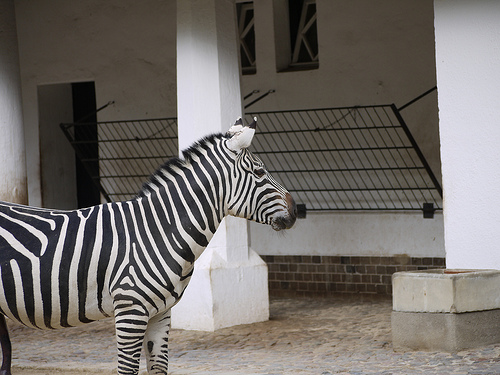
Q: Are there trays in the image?
A: No, there are no trays.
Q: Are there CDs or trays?
A: No, there are no trays or cds.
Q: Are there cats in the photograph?
A: No, there are no cats.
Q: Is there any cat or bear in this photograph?
A: No, there are no cats or bears.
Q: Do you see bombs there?
A: No, there are no bombs.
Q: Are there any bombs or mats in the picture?
A: No, there are no bombs or mats.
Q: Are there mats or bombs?
A: No, there are no bombs or mats.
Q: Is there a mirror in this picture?
A: No, there are no mirrors.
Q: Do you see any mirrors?
A: No, there are no mirrors.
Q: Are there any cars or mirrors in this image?
A: No, there are no mirrors or cars.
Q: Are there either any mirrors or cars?
A: No, there are no mirrors or cars.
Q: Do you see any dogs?
A: No, there are no dogs.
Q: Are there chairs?
A: No, there are no chairs.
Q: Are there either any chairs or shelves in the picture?
A: No, there are no chairs or shelves.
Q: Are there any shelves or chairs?
A: No, there are no chairs or shelves.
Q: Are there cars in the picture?
A: No, there are no cars.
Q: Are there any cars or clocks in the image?
A: No, there are no cars or clocks.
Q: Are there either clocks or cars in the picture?
A: No, there are no cars or clocks.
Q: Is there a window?
A: Yes, there is a window.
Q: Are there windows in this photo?
A: Yes, there is a window.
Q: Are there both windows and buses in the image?
A: No, there is a window but no buses.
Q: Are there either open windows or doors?
A: Yes, there is an open window.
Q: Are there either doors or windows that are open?
A: Yes, the window is open.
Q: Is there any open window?
A: Yes, there is an open window.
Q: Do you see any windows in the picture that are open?
A: Yes, there is a window that is open.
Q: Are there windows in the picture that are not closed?
A: Yes, there is a open window.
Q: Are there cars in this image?
A: No, there are no cars.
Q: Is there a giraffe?
A: No, there are no giraffes.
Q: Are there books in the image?
A: No, there are no books.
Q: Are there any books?
A: No, there are no books.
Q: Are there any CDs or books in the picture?
A: No, there are no books or cds.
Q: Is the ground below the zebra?
A: Yes, the ground is below the zebra.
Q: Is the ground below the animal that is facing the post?
A: Yes, the ground is below the zebra.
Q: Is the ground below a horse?
A: No, the ground is below the zebra.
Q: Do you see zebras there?
A: Yes, there is a zebra.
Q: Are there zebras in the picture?
A: Yes, there is a zebra.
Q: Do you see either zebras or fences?
A: Yes, there is a zebra.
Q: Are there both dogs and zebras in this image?
A: No, there is a zebra but no dogs.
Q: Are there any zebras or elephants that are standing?
A: Yes, the zebra is standing.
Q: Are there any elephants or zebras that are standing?
A: Yes, the zebra is standing.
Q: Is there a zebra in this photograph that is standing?
A: Yes, there is a zebra that is standing.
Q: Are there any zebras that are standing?
A: Yes, there is a zebra that is standing.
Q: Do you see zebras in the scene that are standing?
A: Yes, there is a zebra that is standing.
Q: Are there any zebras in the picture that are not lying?
A: Yes, there is a zebra that is standing.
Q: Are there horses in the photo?
A: No, there are no horses.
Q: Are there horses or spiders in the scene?
A: No, there are no horses or spiders.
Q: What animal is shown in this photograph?
A: The animal is a zebra.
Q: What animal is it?
A: The animal is a zebra.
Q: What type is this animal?
A: This is a zebra.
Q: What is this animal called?
A: This is a zebra.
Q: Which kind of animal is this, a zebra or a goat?
A: This is a zebra.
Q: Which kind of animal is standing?
A: The animal is a zebra.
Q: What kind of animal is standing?
A: The animal is a zebra.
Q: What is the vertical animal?
A: The animal is a zebra.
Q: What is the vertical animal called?
A: The animal is a zebra.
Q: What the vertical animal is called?
A: The animal is a zebra.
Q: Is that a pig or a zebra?
A: That is a zebra.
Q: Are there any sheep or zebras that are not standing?
A: No, there is a zebra but it is standing.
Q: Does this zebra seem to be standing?
A: Yes, the zebra is standing.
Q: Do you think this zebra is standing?
A: Yes, the zebra is standing.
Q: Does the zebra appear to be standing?
A: Yes, the zebra is standing.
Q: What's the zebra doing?
A: The zebra is standing.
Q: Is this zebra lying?
A: No, the zebra is standing.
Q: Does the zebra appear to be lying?
A: No, the zebra is standing.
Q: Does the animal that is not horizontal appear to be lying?
A: No, the zebra is standing.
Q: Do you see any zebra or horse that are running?
A: No, there is a zebra but it is standing.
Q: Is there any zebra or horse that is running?
A: No, there is a zebra but it is standing.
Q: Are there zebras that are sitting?
A: No, there is a zebra but it is standing.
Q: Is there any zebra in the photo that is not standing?
A: No, there is a zebra but it is standing.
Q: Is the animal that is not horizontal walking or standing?
A: The zebra is standing.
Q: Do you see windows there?
A: Yes, there is a window.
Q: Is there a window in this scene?
A: Yes, there is a window.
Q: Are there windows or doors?
A: Yes, there is a window.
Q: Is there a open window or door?
A: Yes, there is an open window.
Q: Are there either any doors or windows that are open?
A: Yes, the window is open.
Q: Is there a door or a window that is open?
A: Yes, the window is open.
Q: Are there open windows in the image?
A: Yes, there is an open window.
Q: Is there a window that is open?
A: Yes, there is a window that is open.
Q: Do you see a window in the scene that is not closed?
A: Yes, there is a open window.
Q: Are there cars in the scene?
A: No, there are no cars.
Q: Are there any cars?
A: No, there are no cars.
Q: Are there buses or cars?
A: No, there are no cars or buses.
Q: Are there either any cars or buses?
A: No, there are no cars or buses.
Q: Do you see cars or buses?
A: No, there are no cars or buses.